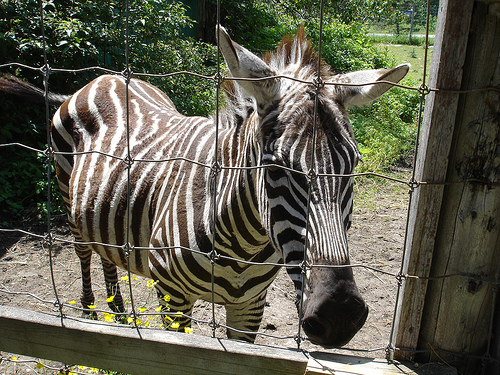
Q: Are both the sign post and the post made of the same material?
A: Yes, both the sign post and the post are made of wood.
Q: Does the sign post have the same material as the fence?
A: Yes, both the sign post and the fence are made of wood.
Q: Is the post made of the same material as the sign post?
A: Yes, both the post and the sign post are made of wood.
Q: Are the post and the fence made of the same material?
A: Yes, both the post and the fence are made of wood.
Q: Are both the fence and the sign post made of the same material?
A: Yes, both the fence and the sign post are made of wood.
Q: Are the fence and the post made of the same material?
A: Yes, both the fence and the post are made of wood.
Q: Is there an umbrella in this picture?
A: No, there are no umbrellas.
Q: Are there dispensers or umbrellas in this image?
A: No, there are no umbrellas or dispensers.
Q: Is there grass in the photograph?
A: Yes, there is grass.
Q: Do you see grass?
A: Yes, there is grass.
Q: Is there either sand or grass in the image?
A: Yes, there is grass.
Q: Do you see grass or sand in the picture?
A: Yes, there is grass.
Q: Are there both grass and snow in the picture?
A: No, there is grass but no snow.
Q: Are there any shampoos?
A: No, there are no shampoos.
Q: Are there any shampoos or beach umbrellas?
A: No, there are no shampoos or beach umbrellas.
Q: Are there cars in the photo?
A: No, there are no cars.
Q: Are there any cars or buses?
A: No, there are no cars or buses.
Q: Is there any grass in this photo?
A: Yes, there is grass.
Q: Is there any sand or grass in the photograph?
A: Yes, there is grass.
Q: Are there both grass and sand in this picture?
A: No, there is grass but no sand.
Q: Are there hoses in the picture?
A: No, there are no hoses.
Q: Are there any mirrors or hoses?
A: No, there are no hoses or mirrors.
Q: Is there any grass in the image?
A: Yes, there is grass.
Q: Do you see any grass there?
A: Yes, there is grass.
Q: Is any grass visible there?
A: Yes, there is grass.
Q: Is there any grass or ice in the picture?
A: Yes, there is grass.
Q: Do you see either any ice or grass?
A: Yes, there is grass.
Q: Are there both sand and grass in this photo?
A: No, there is grass but no sand.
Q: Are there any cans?
A: No, there are no cans.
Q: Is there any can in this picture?
A: No, there are no cans.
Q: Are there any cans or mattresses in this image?
A: No, there are no cans or mattresses.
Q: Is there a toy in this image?
A: No, there are no toys.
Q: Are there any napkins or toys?
A: No, there are no toys or napkins.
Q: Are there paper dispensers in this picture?
A: No, there are no paper dispensers.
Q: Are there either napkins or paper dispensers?
A: No, there are no paper dispensers or napkins.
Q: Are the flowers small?
A: Yes, the flowers are small.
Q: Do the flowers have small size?
A: Yes, the flowers are small.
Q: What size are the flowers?
A: The flowers are small.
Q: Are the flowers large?
A: No, the flowers are small.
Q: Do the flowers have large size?
A: No, the flowers are small.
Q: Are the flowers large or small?
A: The flowers are small.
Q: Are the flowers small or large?
A: The flowers are small.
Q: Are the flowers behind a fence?
A: Yes, the flowers are behind a fence.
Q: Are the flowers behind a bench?
A: No, the flowers are behind a fence.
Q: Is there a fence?
A: Yes, there is a fence.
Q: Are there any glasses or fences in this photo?
A: Yes, there is a fence.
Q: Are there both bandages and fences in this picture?
A: No, there is a fence but no bandages.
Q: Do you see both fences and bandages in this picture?
A: No, there is a fence but no bandages.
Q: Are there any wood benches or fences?
A: Yes, there is a wood fence.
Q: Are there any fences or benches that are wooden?
A: Yes, the fence is wooden.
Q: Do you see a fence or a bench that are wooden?
A: Yes, the fence is wooden.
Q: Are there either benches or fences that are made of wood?
A: Yes, the fence is made of wood.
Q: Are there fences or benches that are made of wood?
A: Yes, the fence is made of wood.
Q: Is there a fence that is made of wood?
A: Yes, there is a fence that is made of wood.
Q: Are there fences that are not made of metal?
A: Yes, there is a fence that is made of wood.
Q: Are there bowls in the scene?
A: No, there are no bowls.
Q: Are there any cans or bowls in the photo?
A: No, there are no bowls or cans.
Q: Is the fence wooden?
A: Yes, the fence is wooden.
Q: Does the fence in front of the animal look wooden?
A: Yes, the fence is wooden.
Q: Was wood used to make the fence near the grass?
A: Yes, the fence is made of wood.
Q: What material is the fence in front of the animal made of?
A: The fence is made of wood.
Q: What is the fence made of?
A: The fence is made of wood.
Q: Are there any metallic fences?
A: No, there is a fence but it is wooden.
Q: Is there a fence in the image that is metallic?
A: No, there is a fence but it is wooden.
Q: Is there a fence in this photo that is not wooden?
A: No, there is a fence but it is wooden.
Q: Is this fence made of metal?
A: No, the fence is made of wood.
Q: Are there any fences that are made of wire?
A: No, there is a fence but it is made of wood.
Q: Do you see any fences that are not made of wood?
A: No, there is a fence but it is made of wood.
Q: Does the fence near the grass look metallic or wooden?
A: The fence is wooden.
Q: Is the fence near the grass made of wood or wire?
A: The fence is made of wood.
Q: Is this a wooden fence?
A: Yes, this is a wooden fence.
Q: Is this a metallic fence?
A: No, this is a wooden fence.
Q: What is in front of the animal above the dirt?
A: The fence is in front of the animal.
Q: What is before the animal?
A: The fence is in front of the animal.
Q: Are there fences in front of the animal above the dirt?
A: Yes, there is a fence in front of the animal.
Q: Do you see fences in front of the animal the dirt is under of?
A: Yes, there is a fence in front of the animal.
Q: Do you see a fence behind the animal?
A: No, the fence is in front of the animal.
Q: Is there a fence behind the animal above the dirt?
A: No, the fence is in front of the animal.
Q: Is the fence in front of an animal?
A: Yes, the fence is in front of an animal.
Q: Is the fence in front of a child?
A: No, the fence is in front of an animal.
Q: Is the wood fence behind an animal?
A: No, the fence is in front of an animal.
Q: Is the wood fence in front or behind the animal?
A: The fence is in front of the animal.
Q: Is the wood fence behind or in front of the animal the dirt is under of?
A: The fence is in front of the animal.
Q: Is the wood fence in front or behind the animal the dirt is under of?
A: The fence is in front of the animal.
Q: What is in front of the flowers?
A: The fence is in front of the flowers.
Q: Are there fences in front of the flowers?
A: Yes, there is a fence in front of the flowers.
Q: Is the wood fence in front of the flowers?
A: Yes, the fence is in front of the flowers.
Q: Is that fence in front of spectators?
A: No, the fence is in front of the flowers.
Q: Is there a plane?
A: No, there are no airplanes.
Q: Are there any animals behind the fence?
A: Yes, there is an animal behind the fence.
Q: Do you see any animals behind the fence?
A: Yes, there is an animal behind the fence.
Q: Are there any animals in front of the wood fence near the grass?
A: No, the animal is behind the fence.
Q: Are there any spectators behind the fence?
A: No, there is an animal behind the fence.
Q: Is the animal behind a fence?
A: Yes, the animal is behind a fence.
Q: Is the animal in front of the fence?
A: No, the animal is behind the fence.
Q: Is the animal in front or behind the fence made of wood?
A: The animal is behind the fence.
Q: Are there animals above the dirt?
A: Yes, there is an animal above the dirt.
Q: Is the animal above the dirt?
A: Yes, the animal is above the dirt.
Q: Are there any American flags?
A: No, there are no American flags.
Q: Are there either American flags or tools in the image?
A: No, there are no American flags or tools.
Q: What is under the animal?
A: The dirt is under the animal.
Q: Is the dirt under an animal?
A: Yes, the dirt is under an animal.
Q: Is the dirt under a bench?
A: No, the dirt is under an animal.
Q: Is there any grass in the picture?
A: Yes, there is grass.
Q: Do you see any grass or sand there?
A: Yes, there is grass.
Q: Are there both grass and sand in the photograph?
A: No, there is grass but no sand.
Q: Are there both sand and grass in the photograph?
A: No, there is grass but no sand.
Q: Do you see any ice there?
A: No, there is no ice.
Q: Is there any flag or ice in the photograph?
A: No, there are no ice or flags.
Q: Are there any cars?
A: No, there are no cars.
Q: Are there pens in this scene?
A: No, there are no pens.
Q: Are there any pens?
A: No, there are no pens.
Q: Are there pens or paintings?
A: No, there are no pens or paintings.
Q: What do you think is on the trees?
A: The leaves are on the trees.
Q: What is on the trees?
A: The leaves are on the trees.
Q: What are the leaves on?
A: The leaves are on the trees.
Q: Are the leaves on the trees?
A: Yes, the leaves are on the trees.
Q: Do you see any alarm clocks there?
A: No, there are no alarm clocks.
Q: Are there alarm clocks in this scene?
A: No, there are no alarm clocks.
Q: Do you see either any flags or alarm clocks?
A: No, there are no alarm clocks or flags.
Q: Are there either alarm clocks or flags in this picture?
A: No, there are no alarm clocks or flags.